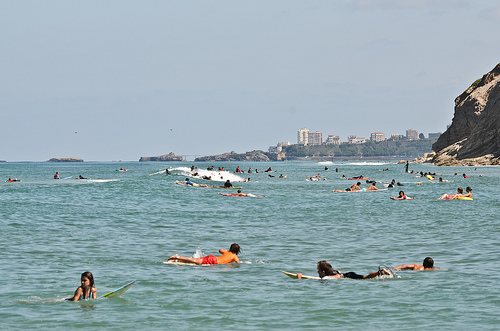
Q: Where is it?
A: This is at the ocean.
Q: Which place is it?
A: It is an ocean.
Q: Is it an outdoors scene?
A: Yes, it is outdoors.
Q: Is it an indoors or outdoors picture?
A: It is outdoors.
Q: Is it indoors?
A: No, it is outdoors.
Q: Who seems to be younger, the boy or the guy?
A: The boy is younger than the guy.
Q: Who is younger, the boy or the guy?
A: The boy is younger than the guy.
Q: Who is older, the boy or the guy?
A: The guy is older than the boy.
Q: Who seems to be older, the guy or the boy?
A: The guy is older than the boy.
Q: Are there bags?
A: No, there are no bags.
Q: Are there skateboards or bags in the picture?
A: No, there are no bags or skateboards.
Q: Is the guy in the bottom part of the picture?
A: Yes, the guy is in the bottom of the image.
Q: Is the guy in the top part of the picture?
A: No, the guy is in the bottom of the image.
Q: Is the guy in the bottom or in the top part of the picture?
A: The guy is in the bottom of the image.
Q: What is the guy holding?
A: The guy is holding the surf board.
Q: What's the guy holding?
A: The guy is holding the surf board.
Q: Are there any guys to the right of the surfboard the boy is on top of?
A: Yes, there is a guy to the right of the surfboard.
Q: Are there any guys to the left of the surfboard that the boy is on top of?
A: No, the guy is to the right of the surf board.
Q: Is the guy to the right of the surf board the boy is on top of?
A: Yes, the guy is to the right of the surfboard.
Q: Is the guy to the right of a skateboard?
A: No, the guy is to the right of the surfboard.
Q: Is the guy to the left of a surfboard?
A: No, the guy is to the right of a surfboard.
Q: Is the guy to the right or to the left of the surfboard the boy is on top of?
A: The guy is to the right of the surfboard.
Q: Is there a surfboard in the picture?
A: Yes, there is a surfboard.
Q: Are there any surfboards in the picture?
A: Yes, there is a surfboard.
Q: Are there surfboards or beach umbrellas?
A: Yes, there is a surfboard.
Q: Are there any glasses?
A: No, there are no glasses.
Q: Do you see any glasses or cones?
A: No, there are no glasses or cones.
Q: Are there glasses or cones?
A: No, there are no glasses or cones.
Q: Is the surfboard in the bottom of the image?
A: Yes, the surfboard is in the bottom of the image.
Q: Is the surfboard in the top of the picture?
A: No, the surfboard is in the bottom of the image.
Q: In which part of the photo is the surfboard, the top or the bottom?
A: The surfboard is in the bottom of the image.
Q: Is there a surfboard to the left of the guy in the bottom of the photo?
A: Yes, there is a surfboard to the left of the guy.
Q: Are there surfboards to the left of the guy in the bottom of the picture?
A: Yes, there is a surfboard to the left of the guy.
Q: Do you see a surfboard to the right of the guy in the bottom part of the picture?
A: No, the surfboard is to the left of the guy.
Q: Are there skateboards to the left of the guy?
A: No, there is a surfboard to the left of the guy.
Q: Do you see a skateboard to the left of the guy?
A: No, there is a surfboard to the left of the guy.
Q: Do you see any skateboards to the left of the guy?
A: No, there is a surfboard to the left of the guy.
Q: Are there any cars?
A: No, there are no cars.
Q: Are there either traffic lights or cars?
A: No, there are no cars or traffic lights.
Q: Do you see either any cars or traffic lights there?
A: No, there are no cars or traffic lights.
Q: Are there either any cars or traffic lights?
A: No, there are no cars or traffic lights.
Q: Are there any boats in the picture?
A: No, there are no boats.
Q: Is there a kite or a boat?
A: No, there are no boats or kites.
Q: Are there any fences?
A: No, there are no fences.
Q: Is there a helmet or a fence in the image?
A: No, there are no fences or helmets.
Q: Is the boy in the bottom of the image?
A: Yes, the boy is in the bottom of the image.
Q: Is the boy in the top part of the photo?
A: No, the boy is in the bottom of the image.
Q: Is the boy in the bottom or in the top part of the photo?
A: The boy is in the bottom of the image.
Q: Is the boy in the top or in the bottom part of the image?
A: The boy is in the bottom of the image.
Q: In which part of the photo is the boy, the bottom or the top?
A: The boy is in the bottom of the image.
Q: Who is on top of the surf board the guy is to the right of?
A: The boy is on top of the surfboard.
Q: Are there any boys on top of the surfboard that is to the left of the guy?
A: Yes, there is a boy on top of the surfboard.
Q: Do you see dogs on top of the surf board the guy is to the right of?
A: No, there is a boy on top of the surfboard.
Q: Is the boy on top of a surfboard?
A: Yes, the boy is on top of a surfboard.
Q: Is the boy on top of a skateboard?
A: No, the boy is on top of a surfboard.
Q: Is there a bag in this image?
A: No, there are no bags.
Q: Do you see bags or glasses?
A: No, there are no bags or glasses.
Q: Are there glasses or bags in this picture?
A: No, there are no bags or glasses.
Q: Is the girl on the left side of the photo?
A: Yes, the girl is on the left of the image.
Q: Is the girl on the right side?
A: No, the girl is on the left of the image.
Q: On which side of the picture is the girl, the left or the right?
A: The girl is on the left of the image.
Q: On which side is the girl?
A: The girl is on the left of the image.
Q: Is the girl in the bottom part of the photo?
A: Yes, the girl is in the bottom of the image.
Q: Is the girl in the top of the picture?
A: No, the girl is in the bottom of the image.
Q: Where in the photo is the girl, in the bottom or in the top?
A: The girl is in the bottom of the image.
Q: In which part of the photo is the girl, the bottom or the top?
A: The girl is in the bottom of the image.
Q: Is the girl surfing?
A: Yes, the girl is surfing.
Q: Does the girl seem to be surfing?
A: Yes, the girl is surfing.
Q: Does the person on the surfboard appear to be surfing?
A: Yes, the girl is surfing.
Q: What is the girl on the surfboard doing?
A: The girl is surfing.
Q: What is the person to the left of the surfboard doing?
A: The girl is surfing.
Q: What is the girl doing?
A: The girl is surfing.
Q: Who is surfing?
A: The girl is surfing.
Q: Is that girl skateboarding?
A: No, the girl is surfing.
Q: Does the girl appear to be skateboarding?
A: No, the girl is surfing.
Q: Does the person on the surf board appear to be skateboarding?
A: No, the girl is surfing.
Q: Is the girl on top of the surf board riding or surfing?
A: The girl is surfing.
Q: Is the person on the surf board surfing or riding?
A: The girl is surfing.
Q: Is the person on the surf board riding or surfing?
A: The girl is surfing.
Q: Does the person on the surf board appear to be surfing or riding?
A: The girl is surfing.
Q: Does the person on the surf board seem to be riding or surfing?
A: The girl is surfing.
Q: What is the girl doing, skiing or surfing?
A: The girl is surfing.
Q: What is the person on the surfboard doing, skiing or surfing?
A: The girl is surfing.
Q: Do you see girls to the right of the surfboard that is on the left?
A: No, the girl is to the left of the surf board.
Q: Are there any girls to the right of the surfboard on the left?
A: No, the girl is to the left of the surf board.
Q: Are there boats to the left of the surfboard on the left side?
A: No, there is a girl to the left of the surfboard.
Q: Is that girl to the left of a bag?
A: No, the girl is to the left of the surfboard.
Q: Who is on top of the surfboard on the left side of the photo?
A: The girl is on top of the surf board.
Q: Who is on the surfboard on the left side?
A: The girl is on the surfboard.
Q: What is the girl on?
A: The girl is on the surfboard.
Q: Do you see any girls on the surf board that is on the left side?
A: Yes, there is a girl on the surf board.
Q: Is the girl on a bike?
A: No, the girl is on the surf board.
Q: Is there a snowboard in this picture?
A: No, there are no snowboards.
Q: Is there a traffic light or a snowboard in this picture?
A: No, there are no snowboards or traffic lights.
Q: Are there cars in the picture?
A: No, there are no cars.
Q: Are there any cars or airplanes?
A: No, there are no cars or airplanes.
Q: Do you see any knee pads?
A: No, there are no knee pads.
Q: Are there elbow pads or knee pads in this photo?
A: No, there are no knee pads or elbow pads.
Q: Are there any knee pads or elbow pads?
A: No, there are no knee pads or elbow pads.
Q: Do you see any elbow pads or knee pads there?
A: No, there are no knee pads or elbow pads.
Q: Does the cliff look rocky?
A: Yes, the cliff is rocky.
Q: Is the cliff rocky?
A: Yes, the cliff is rocky.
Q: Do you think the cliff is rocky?
A: Yes, the cliff is rocky.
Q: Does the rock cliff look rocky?
A: Yes, the cliff is rocky.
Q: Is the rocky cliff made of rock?
A: Yes, the cliff is made of rock.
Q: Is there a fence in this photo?
A: No, there are no fences.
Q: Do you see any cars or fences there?
A: No, there are no fences or cars.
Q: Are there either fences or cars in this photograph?
A: No, there are no fences or cars.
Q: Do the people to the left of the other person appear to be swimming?
A: Yes, the people are swimming.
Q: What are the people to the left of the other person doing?
A: The people are swimming.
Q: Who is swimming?
A: The people are swimming.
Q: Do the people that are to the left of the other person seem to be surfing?
A: No, the people are swimming.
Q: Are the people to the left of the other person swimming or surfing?
A: The people are swimming.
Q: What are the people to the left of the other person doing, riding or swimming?
A: The people are swimming.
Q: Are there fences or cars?
A: No, there are no cars or fences.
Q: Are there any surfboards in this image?
A: Yes, there is a surfboard.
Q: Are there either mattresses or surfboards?
A: Yes, there is a surfboard.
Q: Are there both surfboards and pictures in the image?
A: No, there is a surfboard but no pictures.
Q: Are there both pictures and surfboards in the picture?
A: No, there is a surfboard but no pictures.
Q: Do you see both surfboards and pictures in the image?
A: No, there is a surfboard but no pictures.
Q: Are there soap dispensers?
A: No, there are no soap dispensers.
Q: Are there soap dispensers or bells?
A: No, there are no soap dispensers or bells.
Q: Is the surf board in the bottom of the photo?
A: Yes, the surf board is in the bottom of the image.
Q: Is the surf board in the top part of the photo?
A: No, the surf board is in the bottom of the image.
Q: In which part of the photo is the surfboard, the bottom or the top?
A: The surfboard is in the bottom of the image.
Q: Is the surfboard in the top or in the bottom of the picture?
A: The surfboard is in the bottom of the image.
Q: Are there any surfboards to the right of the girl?
A: Yes, there is a surfboard to the right of the girl.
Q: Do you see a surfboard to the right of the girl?
A: Yes, there is a surfboard to the right of the girl.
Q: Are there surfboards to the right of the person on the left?
A: Yes, there is a surfboard to the right of the girl.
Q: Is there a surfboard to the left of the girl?
A: No, the surfboard is to the right of the girl.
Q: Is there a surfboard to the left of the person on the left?
A: No, the surfboard is to the right of the girl.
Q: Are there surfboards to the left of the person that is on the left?
A: No, the surfboard is to the right of the girl.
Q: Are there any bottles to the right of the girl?
A: No, there is a surfboard to the right of the girl.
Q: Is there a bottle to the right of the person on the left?
A: No, there is a surfboard to the right of the girl.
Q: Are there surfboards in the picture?
A: Yes, there is a surfboard.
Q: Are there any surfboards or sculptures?
A: Yes, there is a surfboard.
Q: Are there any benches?
A: No, there are no benches.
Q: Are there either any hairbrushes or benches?
A: No, there are no benches or hairbrushes.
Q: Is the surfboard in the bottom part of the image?
A: Yes, the surfboard is in the bottom of the image.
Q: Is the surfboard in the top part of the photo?
A: No, the surfboard is in the bottom of the image.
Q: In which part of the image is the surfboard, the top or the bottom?
A: The surfboard is in the bottom of the image.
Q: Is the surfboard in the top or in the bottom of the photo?
A: The surfboard is in the bottom of the image.